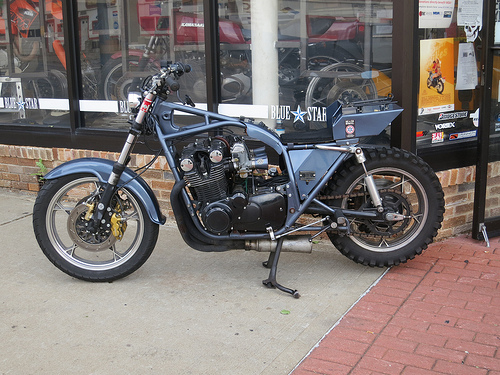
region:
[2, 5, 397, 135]
windows of store front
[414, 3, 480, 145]
papers on glass window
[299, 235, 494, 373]
red bricks on ground surface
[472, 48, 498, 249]
glass door propped open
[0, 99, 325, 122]
line and logo on windows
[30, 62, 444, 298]
motorcycle parked on sidewalk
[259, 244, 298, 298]
kickstand under parked bike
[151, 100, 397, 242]
blue body of bike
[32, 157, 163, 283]
fender on bike tire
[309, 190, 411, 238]
chain on back of bike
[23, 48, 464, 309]
motorcyle on the sidewalk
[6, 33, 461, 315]
motorcycle on sidewalk is black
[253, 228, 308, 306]
motorcycle kickstand is down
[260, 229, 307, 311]
motorcycle kickstand is black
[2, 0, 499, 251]
storefront behind black motorcycle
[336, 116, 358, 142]
sticker on motorcycle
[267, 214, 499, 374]
part of sidewalk is red brick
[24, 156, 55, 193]
portion of weed growing by wall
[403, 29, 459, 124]
poster on store window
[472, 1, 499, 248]
door to store is open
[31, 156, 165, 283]
Front wheel and fender of a blue motorcycle.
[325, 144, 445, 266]
Rear wheel of a motorcycle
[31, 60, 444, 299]
A blue motorcycle parked on the road.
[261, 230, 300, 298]
A kickstand holding up a motorcycle.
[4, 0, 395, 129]
Window of a store.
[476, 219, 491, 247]
Silver doorstop on the corner of a door.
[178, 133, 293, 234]
Engine of a motorbike.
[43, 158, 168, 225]
Front fender of a blue motorbike.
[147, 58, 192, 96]
Handlebars on a motorbike.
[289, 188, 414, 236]
Chain on a motorbike.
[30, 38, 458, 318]
a gray motor bike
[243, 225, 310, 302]
a black kick stand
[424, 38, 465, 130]
a yellow sign in window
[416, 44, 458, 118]
a motor bike on sign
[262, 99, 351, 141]
white letters on window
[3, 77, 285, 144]
white line on window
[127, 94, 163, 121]
red area on bike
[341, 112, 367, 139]
a black and white sticker on bike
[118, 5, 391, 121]
a red bike seen through window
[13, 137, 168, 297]
front tire of bike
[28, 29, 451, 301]
motorcycle parked outside a motorcycle shop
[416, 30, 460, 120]
a poster of a motorcycle hanging on the window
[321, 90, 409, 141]
motorcycle has a storage compartment in the rear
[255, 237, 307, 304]
motorcycle has a double kickstand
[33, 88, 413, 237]
motorcycle has steel gray detailing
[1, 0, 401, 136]
many motorcycles on display inside the shop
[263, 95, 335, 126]
name of the shop is Blue Star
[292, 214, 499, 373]
walkway leading to the door is cobblestone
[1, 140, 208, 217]
low brick wall in front of the shop